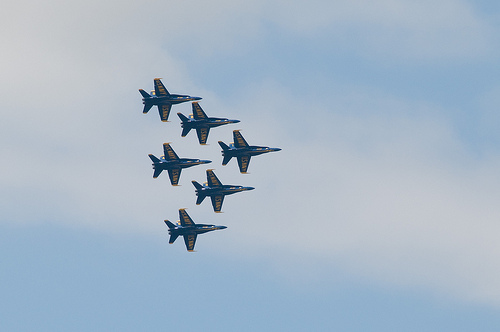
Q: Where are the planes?
A: Sky.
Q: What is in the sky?
A: Planes.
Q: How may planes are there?
A: 6.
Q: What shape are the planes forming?
A: Triangle.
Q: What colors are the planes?
A: Blue and yellow.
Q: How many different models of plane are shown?
A: One.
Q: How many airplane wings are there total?
A: 12.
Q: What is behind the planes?
A: Clouds.